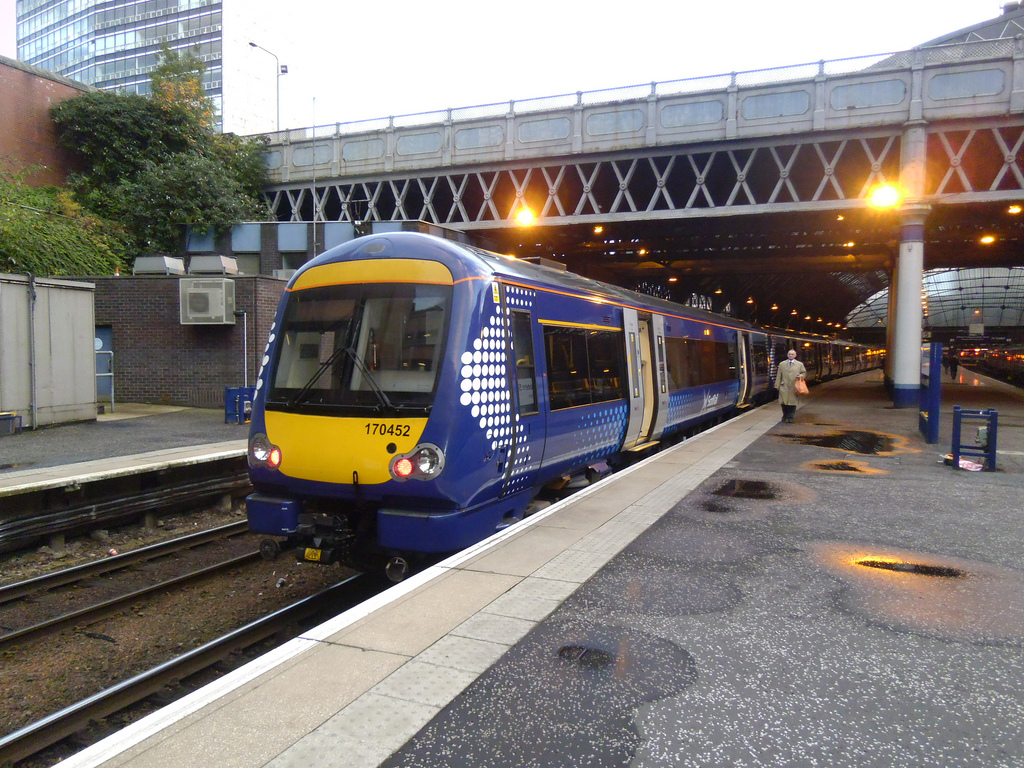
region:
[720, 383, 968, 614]
Puddles on the asphalt.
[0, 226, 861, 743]
Blue and yellow train on tracks.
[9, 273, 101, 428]
Beige shed with sliding doors.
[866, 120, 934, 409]
Large white column with light.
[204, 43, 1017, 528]
Train is under the overpass.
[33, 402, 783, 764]
Concrete near train with white stripe.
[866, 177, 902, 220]
A light on the bridge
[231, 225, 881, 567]
A train coming out of a tunnel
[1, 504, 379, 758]
Tracks on the ground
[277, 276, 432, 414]
The front window of the train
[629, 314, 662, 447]
The door of the train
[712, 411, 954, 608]
Puddles on the platform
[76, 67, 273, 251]
Plants by the bridge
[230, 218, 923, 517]
the train is waiting at a station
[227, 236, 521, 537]
the train is blue and yellow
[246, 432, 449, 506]
the headlights on front of the train are on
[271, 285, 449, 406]
the front windows of the train have windshield wipers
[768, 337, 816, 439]
a man is walking on the train platform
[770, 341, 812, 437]
the man is wearing a beige trench coat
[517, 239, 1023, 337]
the station has lights on the ceiling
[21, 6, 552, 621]
a building is near the train station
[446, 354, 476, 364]
dot on the train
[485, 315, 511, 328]
dot on the train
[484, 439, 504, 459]
dot on the train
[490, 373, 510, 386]
dot on the train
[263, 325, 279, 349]
dot on the train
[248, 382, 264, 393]
dot on the train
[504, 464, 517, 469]
dot on the train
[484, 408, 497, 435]
dot on the train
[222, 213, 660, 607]
train is yellow, white and blue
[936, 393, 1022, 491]
bars on sidewalk are blue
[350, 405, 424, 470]
numbers on train are black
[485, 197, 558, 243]
There is a light above the train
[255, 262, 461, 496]
The front of the train has yellow on it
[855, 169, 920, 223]
There is a light above a post on the bridge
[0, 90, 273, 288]
There are bushes by the bridge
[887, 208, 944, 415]
The post holding up the bridge is white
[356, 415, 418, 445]
The train has the numbers "170452" on the front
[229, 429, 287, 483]
The train has a right front light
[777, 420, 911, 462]
There is a large puddle by the person walking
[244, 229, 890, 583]
A blue and yellow train.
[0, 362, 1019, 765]
A train track.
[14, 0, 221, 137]
A building in the distance.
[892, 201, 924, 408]
A blue and white column.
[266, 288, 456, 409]
A windshield of a train.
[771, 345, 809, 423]
A man in a rain coat.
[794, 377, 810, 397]
An orange bag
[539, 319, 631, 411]
Long window of train.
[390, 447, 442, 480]
Round headlight of train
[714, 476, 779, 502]
A puddle of water.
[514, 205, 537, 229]
Orange glowing light to left of train.